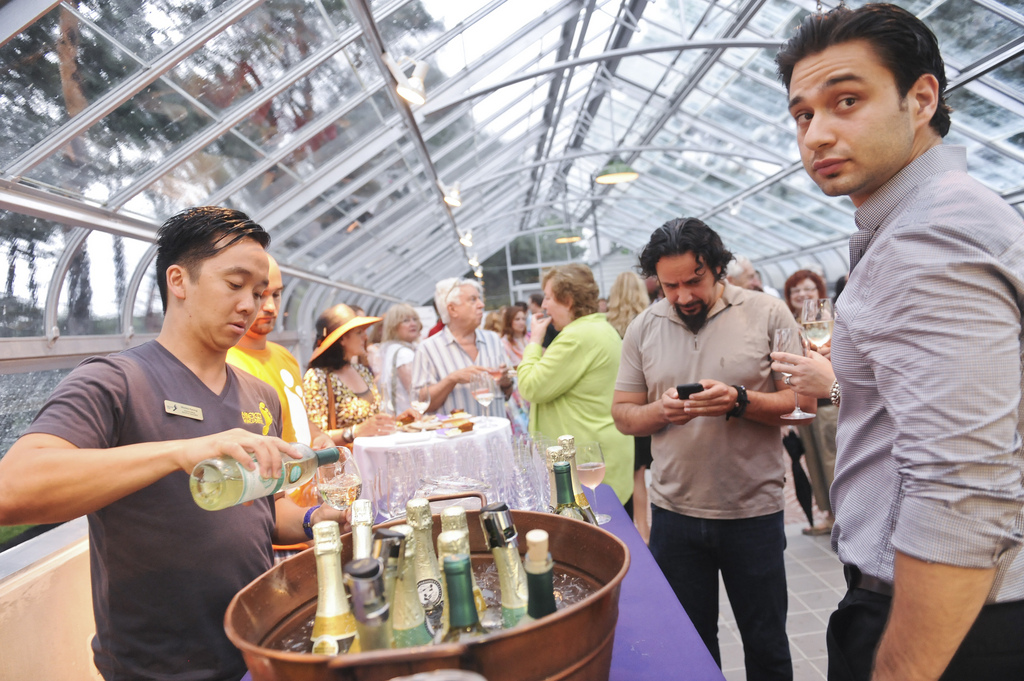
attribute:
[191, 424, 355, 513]
bottle — clear, brown, white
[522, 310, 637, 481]
jacket — green, lime, long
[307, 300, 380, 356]
hat — orange, brown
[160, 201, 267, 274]
hair — dark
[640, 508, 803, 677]
pants — black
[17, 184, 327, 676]
man — brown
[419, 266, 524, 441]
man — old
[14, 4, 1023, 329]
ceiling — grey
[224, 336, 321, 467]
shirt — orange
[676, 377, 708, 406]
phone — black, short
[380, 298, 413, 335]
hair — grey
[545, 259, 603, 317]
hair — short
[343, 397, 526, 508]
table — round, short, purple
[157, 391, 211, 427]
tag — brown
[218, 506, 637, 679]
bucket — brown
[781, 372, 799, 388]
ring — silver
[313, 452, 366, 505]
glass — clear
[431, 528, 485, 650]
bottle — closed